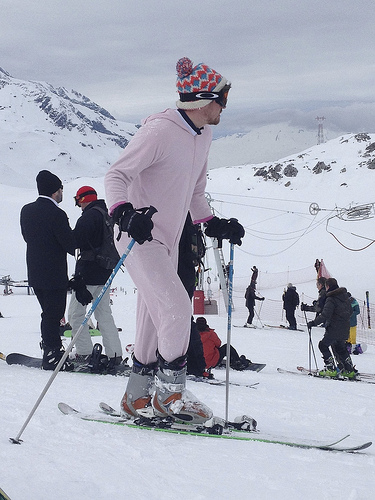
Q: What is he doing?
A: Skiing.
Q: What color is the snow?
A: White.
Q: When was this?
A: Daytime.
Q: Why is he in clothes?
A: To keep warm.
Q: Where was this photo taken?
A: Ski slope.